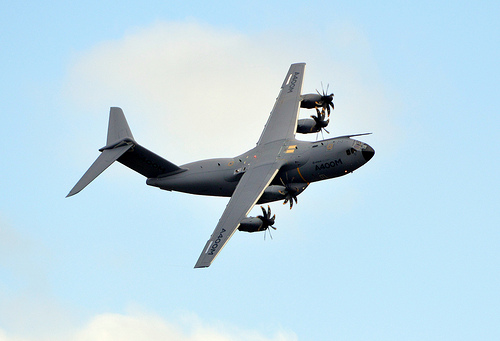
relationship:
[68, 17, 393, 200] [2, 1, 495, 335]
cloud in sky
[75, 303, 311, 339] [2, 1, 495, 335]
cloud in sky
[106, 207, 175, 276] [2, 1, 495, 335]
clouds in sky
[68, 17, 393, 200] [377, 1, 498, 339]
cloud in sky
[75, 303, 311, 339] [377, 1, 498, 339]
cloud in sky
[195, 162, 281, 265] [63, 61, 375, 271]
wing on airplane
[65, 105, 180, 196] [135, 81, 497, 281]
tail of plane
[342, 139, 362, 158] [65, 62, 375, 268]
cockpit of plane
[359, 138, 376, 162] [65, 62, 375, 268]
nose of plane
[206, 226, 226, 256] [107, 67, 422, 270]
mark of airplane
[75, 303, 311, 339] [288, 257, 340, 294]
cloud in sky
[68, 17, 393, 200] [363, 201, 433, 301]
cloud in blue sky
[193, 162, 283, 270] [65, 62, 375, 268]
wing of plane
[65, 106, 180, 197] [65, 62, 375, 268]
tail of plane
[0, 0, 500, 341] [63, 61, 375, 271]
blue sky behind airplane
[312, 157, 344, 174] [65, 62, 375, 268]
writing on plane